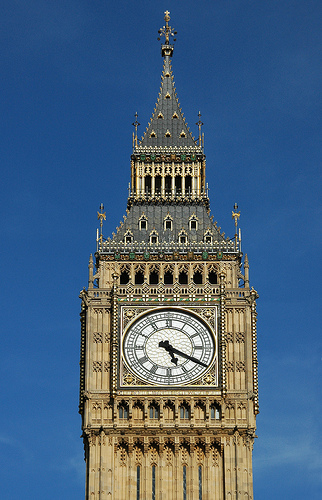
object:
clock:
[117, 302, 223, 391]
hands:
[158, 340, 208, 367]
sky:
[1, 4, 321, 500]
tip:
[157, 10, 178, 57]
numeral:
[165, 319, 172, 327]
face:
[122, 311, 216, 386]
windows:
[144, 173, 153, 197]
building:
[78, 10, 260, 500]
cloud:
[254, 428, 321, 478]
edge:
[131, 109, 141, 148]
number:
[180, 323, 187, 331]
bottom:
[80, 433, 258, 500]